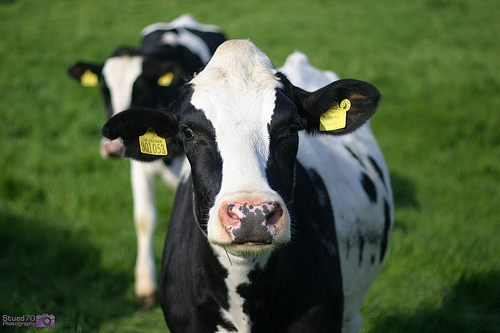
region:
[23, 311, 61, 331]
this is a camera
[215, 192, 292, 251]
this is a nose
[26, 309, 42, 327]
this is the number 0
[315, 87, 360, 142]
this is a tag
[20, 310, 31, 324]
this is the number 7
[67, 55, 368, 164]
these are the tags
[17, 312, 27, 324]
this is the letter D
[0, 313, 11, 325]
this is the letter S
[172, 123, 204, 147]
this is an eye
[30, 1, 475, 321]
The cows are wearing some ear tags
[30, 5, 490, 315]
The cows are looking for food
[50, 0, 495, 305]
The cows are male and female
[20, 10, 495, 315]
Some cows are standing in the grass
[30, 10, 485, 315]
The cows are owned by a farmer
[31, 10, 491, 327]
The cows are grown for their meat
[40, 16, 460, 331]
The cows are out in the daytime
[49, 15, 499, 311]
The cows are enjoying the day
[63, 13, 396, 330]
Two cows in the grass.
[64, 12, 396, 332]
Cows on the grass.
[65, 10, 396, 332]
Cows with yellow tags.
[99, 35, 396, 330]
A black and white cow.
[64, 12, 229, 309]
A small blurry cow.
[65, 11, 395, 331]
Cows in a meadow.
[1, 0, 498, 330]
Grass on the ground.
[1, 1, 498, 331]
Blurry green grass.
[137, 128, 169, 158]
A tag on a cows ear.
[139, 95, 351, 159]
Two tags on a cow.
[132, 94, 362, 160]
tags in a cow's ears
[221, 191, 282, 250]
pink and black spotted nose on a cow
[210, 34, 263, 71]
white lump on the head of a cow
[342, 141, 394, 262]
black spots on white coat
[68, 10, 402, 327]
two cows in a field together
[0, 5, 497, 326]
grassy green field outside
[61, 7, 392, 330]
two black and white cows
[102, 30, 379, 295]
a cow head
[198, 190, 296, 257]
snout of a dairy cow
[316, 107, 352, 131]
a tag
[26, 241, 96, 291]
a shadow on the grass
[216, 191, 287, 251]
the cows nose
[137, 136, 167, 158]
yellow tag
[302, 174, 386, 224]
the cow is black and white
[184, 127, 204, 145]
right eye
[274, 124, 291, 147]
left eye of the cow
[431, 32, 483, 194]
a field of green grass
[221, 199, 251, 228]
nose is pink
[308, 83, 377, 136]
a black ear